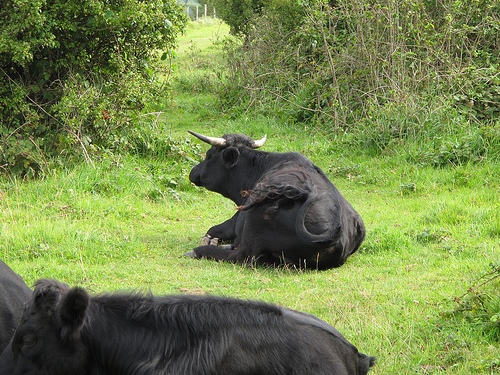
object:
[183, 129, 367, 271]
bull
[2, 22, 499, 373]
ground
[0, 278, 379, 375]
bull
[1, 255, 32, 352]
bull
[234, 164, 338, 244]
tail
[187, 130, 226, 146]
horn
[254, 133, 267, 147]
horn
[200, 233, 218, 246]
hoof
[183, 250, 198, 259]
hoof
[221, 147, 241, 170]
ear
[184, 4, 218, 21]
fence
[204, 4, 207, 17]
post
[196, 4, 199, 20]
post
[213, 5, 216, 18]
post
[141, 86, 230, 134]
passage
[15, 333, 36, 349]
eye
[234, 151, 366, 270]
fur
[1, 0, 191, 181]
brush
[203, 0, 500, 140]
brush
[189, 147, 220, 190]
face